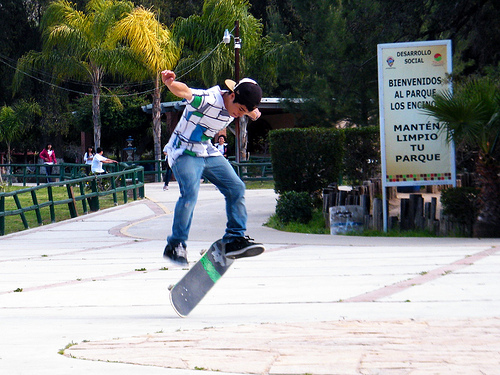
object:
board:
[166, 237, 242, 320]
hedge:
[267, 124, 382, 194]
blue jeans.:
[167, 150, 244, 241]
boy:
[157, 65, 264, 265]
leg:
[216, 160, 253, 239]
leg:
[163, 163, 199, 235]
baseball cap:
[223, 76, 258, 108]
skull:
[212, 239, 232, 269]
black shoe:
[220, 235, 265, 260]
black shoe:
[163, 230, 190, 265]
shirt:
[166, 81, 262, 168]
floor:
[1, 182, 497, 374]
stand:
[371, 177, 403, 229]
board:
[376, 36, 456, 231]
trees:
[12, 1, 177, 162]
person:
[36, 139, 61, 175]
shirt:
[36, 148, 51, 163]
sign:
[374, 38, 457, 234]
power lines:
[3, 55, 215, 99]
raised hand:
[159, 67, 181, 88]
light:
[219, 27, 233, 47]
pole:
[219, 16, 251, 179]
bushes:
[268, 122, 378, 220]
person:
[82, 140, 117, 210]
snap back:
[223, 77, 268, 105]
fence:
[0, 162, 145, 235]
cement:
[2, 180, 278, 372]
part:
[398, 56, 438, 116]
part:
[327, 321, 375, 349]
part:
[369, 160, 409, 233]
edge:
[165, 286, 194, 314]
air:
[0, 1, 498, 374]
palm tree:
[437, 48, 490, 229]